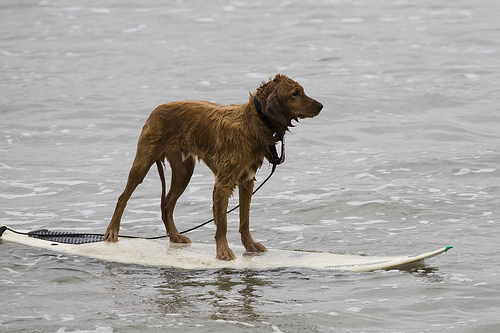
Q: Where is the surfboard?
A: Water.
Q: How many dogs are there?
A: One.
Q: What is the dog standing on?
A: Surfboard.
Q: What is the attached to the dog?
A: Cable.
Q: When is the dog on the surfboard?
A: Daytime.